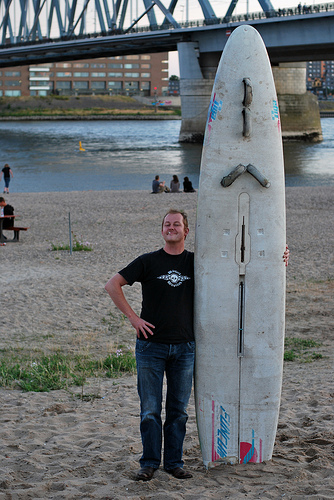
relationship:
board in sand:
[188, 22, 291, 473] [0, 188, 332, 498]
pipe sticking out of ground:
[68, 212, 71, 256] [0, 189, 333, 498]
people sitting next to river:
[151, 172, 196, 191] [0, 116, 334, 193]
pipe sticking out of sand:
[61, 206, 82, 256] [0, 182, 328, 393]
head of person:
[161, 209, 188, 241] [105, 207, 289, 478]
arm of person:
[82, 247, 155, 345] [89, 207, 218, 482]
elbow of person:
[105, 280, 111, 298] [149, 201, 195, 265]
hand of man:
[129, 315, 156, 341] [102, 203, 195, 484]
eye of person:
[163, 222, 170, 227] [105, 207, 289, 478]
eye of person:
[171, 218, 185, 233] [86, 203, 235, 467]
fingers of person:
[281, 243, 290, 265] [105, 207, 289, 478]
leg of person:
[162, 342, 194, 477] [105, 207, 289, 478]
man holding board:
[102, 203, 203, 484] [188, 22, 291, 473]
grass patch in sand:
[49, 240, 92, 250] [0, 188, 332, 498]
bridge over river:
[0, 2, 332, 144] [0, 116, 334, 193]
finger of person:
[139, 325, 148, 340] [104, 211, 194, 481]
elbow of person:
[103, 280, 111, 290] [105, 207, 289, 478]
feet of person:
[135, 464, 154, 483] [105, 207, 289, 478]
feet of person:
[161, 463, 194, 481] [105, 207, 289, 478]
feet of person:
[130, 463, 158, 482] [105, 207, 289, 478]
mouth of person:
[165, 228, 177, 234] [106, 171, 202, 430]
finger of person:
[280, 245, 292, 265] [105, 209, 202, 480]